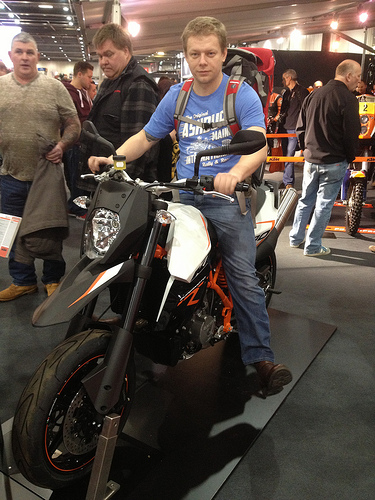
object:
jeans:
[288, 154, 349, 256]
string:
[75, 87, 86, 110]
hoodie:
[61, 80, 96, 126]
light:
[84, 205, 120, 259]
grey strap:
[175, 114, 235, 131]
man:
[284, 39, 363, 262]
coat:
[294, 79, 362, 168]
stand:
[0, 302, 342, 498]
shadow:
[218, 418, 250, 454]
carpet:
[301, 265, 375, 479]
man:
[87, 15, 294, 400]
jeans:
[163, 173, 276, 370]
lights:
[355, 8, 372, 28]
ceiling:
[78, 1, 349, 50]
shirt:
[142, 70, 272, 192]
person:
[1, 24, 80, 308]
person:
[61, 45, 101, 129]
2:
[362, 103, 370, 113]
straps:
[221, 66, 243, 136]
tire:
[343, 176, 366, 237]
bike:
[336, 89, 375, 237]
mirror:
[225, 128, 266, 159]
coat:
[9, 134, 71, 269]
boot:
[251, 355, 294, 398]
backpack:
[173, 45, 278, 226]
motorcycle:
[7, 117, 311, 495]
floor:
[0, 189, 375, 490]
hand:
[213, 166, 241, 198]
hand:
[44, 141, 65, 166]